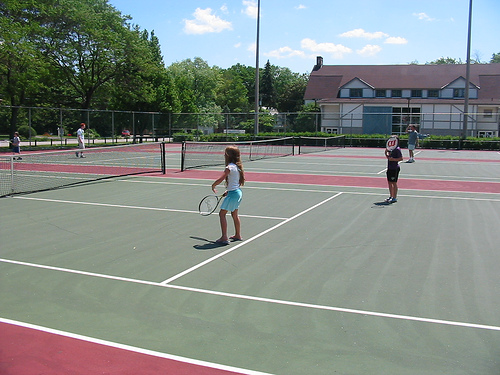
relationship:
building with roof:
[301, 50, 499, 140] [307, 53, 497, 103]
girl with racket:
[209, 145, 246, 245] [194, 183, 231, 220]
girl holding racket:
[209, 145, 246, 245] [188, 187, 220, 227]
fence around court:
[5, 92, 499, 152] [5, 129, 496, 375]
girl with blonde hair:
[209, 145, 246, 245] [222, 145, 246, 189]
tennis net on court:
[300, 129, 348, 154] [5, 129, 496, 375]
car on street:
[119, 128, 127, 139] [7, 125, 187, 144]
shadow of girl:
[197, 227, 268, 274] [194, 144, 261, 248]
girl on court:
[209, 145, 246, 245] [5, 129, 496, 375]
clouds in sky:
[258, 51, 406, 94] [360, 7, 462, 52]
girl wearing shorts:
[371, 123, 405, 209] [222, 190, 244, 215]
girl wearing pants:
[201, 145, 262, 245] [219, 187, 243, 212]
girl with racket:
[209, 145, 246, 245] [189, 183, 234, 224]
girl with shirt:
[209, 145, 246, 245] [221, 163, 243, 193]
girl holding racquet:
[209, 145, 246, 245] [383, 135, 400, 152]